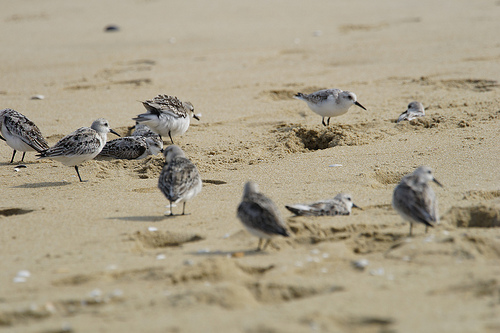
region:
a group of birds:
[1, 78, 488, 266]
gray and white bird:
[288, 83, 375, 130]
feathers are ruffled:
[133, 88, 188, 123]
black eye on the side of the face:
[103, 120, 109, 127]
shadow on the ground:
[17, 173, 72, 193]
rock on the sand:
[26, 91, 49, 102]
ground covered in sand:
[1, 1, 496, 330]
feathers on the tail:
[33, 147, 48, 159]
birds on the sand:
[2, 74, 497, 276]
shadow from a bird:
[9, 168, 76, 193]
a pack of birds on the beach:
[3, 3, 495, 330]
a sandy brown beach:
[233, 121, 324, 186]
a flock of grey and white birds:
[3, 82, 478, 241]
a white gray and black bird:
[293, 82, 366, 134]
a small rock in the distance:
[102, 9, 127, 43]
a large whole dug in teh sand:
[266, 118, 339, 168]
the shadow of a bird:
[19, 172, 91, 207]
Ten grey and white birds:
[5, 74, 452, 246]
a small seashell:
[1, 258, 45, 289]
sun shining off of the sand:
[211, 16, 378, 78]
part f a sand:
[346, 252, 437, 311]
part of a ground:
[77, 233, 114, 276]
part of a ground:
[95, 230, 133, 261]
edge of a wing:
[240, 203, 270, 240]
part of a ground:
[66, 223, 108, 300]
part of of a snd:
[99, 178, 169, 265]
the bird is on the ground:
[292, 94, 368, 125]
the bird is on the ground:
[393, 165, 448, 232]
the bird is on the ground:
[236, 184, 288, 240]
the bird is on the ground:
[163, 143, 203, 210]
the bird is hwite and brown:
[298, 89, 366, 121]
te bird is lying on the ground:
[286, 190, 371, 225]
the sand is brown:
[58, 224, 392, 332]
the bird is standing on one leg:
[71, 164, 96, 189]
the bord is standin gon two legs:
[12, 147, 32, 167]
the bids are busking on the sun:
[8, 37, 499, 329]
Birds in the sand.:
[1, 85, 444, 252]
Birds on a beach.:
[0, 85, 446, 254]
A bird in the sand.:
[37, 117, 121, 185]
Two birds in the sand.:
[291, 84, 425, 129]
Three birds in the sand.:
[235, 163, 444, 252]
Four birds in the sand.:
[35, 93, 202, 218]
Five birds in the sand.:
[1, 93, 202, 217]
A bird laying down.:
[284, 190, 363, 219]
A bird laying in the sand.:
[283, 188, 362, 218]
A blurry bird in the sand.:
[234, 179, 294, 252]